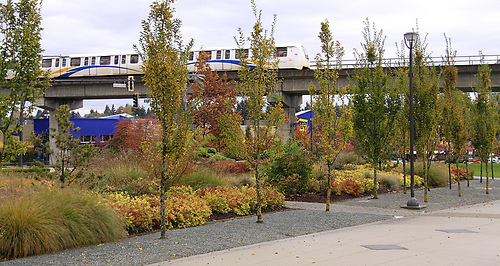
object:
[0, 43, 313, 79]
train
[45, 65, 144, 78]
design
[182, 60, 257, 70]
design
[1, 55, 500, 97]
bridge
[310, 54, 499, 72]
rail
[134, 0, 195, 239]
tree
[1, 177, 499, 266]
sidewalk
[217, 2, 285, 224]
tree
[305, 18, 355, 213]
tree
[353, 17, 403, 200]
tree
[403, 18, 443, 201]
tree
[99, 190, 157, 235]
bush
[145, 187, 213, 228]
bush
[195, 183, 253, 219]
bush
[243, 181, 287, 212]
bush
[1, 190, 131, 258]
bush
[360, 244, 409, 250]
manhole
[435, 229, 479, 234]
manhole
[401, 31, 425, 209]
lightpost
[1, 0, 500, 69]
sky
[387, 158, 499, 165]
lot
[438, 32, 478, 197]
tree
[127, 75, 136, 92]
traffic-light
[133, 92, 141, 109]
traffic-light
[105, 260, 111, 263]
leaf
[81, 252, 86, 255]
leaf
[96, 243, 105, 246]
leaf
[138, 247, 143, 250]
leaf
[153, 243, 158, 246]
leaf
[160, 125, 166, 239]
trunk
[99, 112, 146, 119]
roof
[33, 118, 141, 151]
building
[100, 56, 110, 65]
window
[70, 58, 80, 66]
window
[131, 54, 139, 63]
window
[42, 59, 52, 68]
window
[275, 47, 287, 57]
window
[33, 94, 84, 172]
support